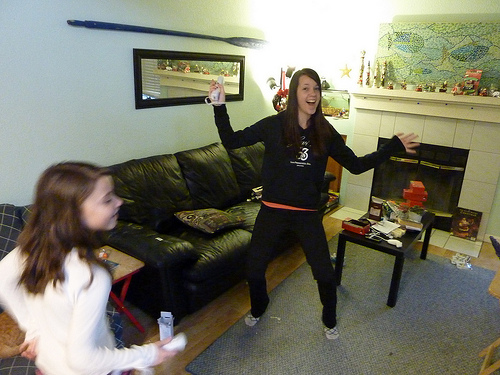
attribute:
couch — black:
[94, 141, 335, 326]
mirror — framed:
[134, 46, 248, 112]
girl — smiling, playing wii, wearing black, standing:
[204, 67, 421, 342]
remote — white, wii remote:
[208, 75, 225, 106]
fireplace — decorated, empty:
[329, 86, 500, 263]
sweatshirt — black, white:
[211, 104, 409, 208]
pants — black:
[244, 207, 342, 330]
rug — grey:
[182, 229, 499, 375]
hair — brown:
[281, 67, 338, 160]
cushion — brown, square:
[172, 206, 247, 234]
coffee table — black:
[331, 200, 436, 310]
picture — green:
[370, 18, 499, 96]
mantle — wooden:
[348, 81, 499, 128]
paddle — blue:
[65, 16, 276, 60]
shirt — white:
[0, 240, 159, 373]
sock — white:
[242, 312, 262, 328]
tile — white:
[419, 114, 461, 148]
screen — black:
[369, 149, 469, 210]